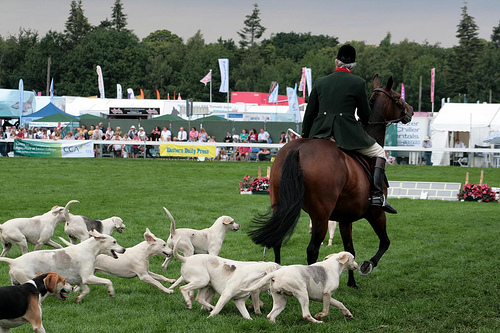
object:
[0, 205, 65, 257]
dog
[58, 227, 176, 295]
dog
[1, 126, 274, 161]
crownd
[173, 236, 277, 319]
dog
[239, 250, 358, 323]
dog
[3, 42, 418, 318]
horse jocket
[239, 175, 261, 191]
flowers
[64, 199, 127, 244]
dog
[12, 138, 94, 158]
banners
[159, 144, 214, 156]
banners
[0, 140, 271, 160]
railing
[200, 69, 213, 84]
flag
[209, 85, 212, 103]
pole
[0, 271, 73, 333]
beagle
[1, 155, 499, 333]
ground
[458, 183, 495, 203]
bush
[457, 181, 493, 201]
flowers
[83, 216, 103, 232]
black spot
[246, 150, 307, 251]
tail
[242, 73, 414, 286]
brown horse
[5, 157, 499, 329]
turf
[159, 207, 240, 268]
dog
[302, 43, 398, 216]
man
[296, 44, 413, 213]
jockey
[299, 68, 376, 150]
jacket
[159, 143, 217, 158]
banner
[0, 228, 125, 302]
dog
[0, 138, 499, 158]
barrier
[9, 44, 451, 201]
sport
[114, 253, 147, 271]
fur